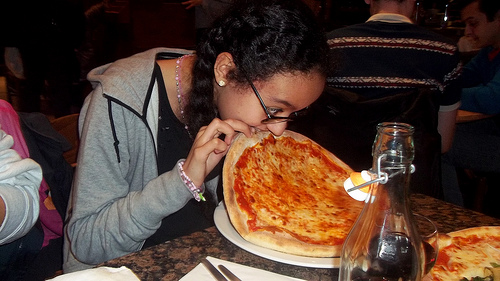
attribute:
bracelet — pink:
[178, 163, 202, 200]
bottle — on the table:
[335, 113, 429, 278]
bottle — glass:
[349, 113, 449, 280]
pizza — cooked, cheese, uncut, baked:
[418, 220, 498, 279]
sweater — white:
[0, 125, 45, 243]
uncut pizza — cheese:
[217, 125, 402, 252]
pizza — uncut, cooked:
[224, 109, 429, 273]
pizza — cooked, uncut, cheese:
[221, 125, 391, 257]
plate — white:
[212, 203, 339, 271]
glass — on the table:
[380, 226, 441, 272]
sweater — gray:
[57, 44, 222, 274]